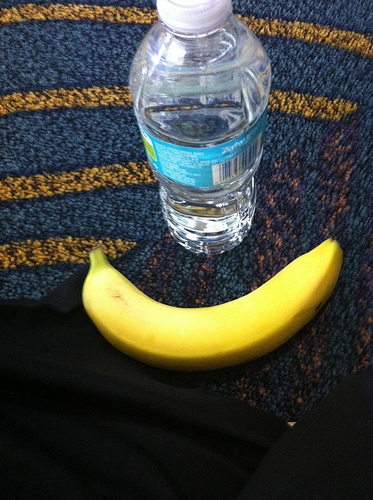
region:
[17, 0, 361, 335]
what a healthy snack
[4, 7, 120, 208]
the blue and yellow carpet is cool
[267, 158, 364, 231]
this carpet has a lot of different colors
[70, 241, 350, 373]
nice ripe bannana to eat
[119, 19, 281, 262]
nice refreshing water in a water bottle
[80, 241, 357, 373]
yellow bannana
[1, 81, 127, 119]
yellow strip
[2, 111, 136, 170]
blue strip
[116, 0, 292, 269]
water bottle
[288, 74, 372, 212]
two different carpets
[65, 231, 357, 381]
Ripe yellow banana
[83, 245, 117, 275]
Tip of the banana is green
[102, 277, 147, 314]
Brown speckled bruises on the banana peel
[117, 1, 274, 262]
View of the top of the water bottle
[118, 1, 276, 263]
water bottle on the carpet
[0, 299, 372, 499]
soft black smooth material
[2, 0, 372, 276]
Yellow wavey line in the carpet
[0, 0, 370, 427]
Multi colored carpet flooring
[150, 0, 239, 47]
unopened bottle top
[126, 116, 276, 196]
Blue green and white label on the water bottle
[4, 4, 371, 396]
blue carpet with yellow stripes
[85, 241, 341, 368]
a yellow banana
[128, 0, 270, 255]
a plastic bottle of water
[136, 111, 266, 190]
a light blue label on the bottle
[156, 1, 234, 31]
white plastic bottle cap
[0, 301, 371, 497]
black pants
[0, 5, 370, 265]
four yellow stripes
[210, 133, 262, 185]
white barcode with blue print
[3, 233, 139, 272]
shortest yellow line in the carpet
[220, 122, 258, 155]
Zephyrhills written in white on bottle label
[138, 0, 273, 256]
plastic water bottle on rug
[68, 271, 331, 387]
yellow banana on rug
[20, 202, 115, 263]
yellow stripes on rug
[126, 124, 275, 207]
blue label on bottle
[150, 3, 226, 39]
white cap on water bottle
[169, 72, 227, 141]
fresh water in bottle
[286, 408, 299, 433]
small white triangle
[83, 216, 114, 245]
blue threads in carpet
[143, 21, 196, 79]
light reflecting off bottle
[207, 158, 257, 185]
barcode on label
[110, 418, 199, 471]
black fabric on the surface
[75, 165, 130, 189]
gold and black thread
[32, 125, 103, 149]
blue yarn on the surface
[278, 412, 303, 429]
tiny white spot on the surface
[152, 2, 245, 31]
water bottle white lid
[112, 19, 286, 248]
clear water bottle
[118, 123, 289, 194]
blue label on water bottle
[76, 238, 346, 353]
long yellow banana on surface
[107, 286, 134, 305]
brown stain on yellow banana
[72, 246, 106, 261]
green stem on yellow banana